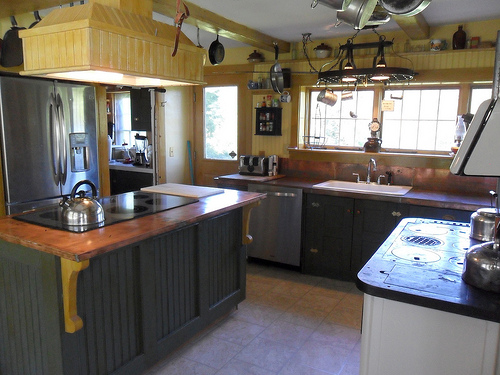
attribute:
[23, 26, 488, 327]
kitchen — busy, large, big, yellow, brown, open, crowded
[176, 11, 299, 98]
pans — hanging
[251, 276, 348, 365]
floor — tan, brown, here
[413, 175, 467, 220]
counter — brown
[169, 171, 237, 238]
island — brown, orange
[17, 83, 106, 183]
fridge — silver, closed, metal, new, close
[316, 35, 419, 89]
pot rack — black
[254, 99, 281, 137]
spice rack — black